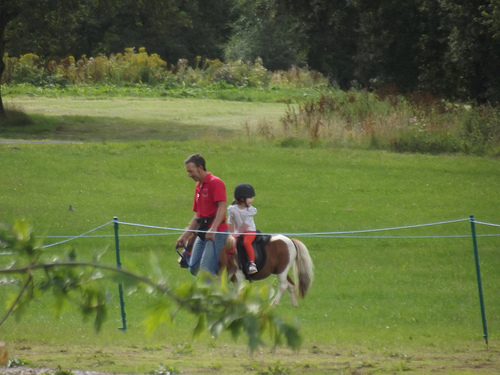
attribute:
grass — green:
[6, 137, 496, 371]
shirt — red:
[192, 180, 221, 217]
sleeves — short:
[208, 173, 228, 200]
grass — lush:
[272, 156, 473, 216]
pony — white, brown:
[194, 234, 316, 298]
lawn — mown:
[279, 145, 499, 235]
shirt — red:
[193, 171, 228, 216]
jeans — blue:
[193, 226, 225, 300]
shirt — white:
[223, 200, 260, 231]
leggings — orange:
[223, 226, 269, 276]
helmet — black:
[232, 180, 261, 206]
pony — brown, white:
[211, 214, 319, 289]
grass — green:
[330, 173, 490, 357]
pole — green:
[414, 228, 497, 325]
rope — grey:
[144, 223, 481, 259]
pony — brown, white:
[151, 218, 355, 270]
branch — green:
[58, 213, 303, 363]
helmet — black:
[234, 170, 252, 206]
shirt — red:
[177, 173, 260, 236]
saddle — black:
[232, 218, 283, 276]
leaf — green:
[218, 322, 359, 373]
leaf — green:
[224, 323, 278, 356]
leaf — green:
[262, 283, 301, 301]